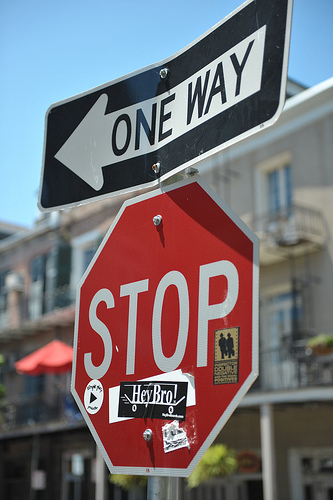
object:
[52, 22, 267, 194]
arrow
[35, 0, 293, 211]
sign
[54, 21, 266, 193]
words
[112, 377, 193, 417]
sticker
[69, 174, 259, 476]
sign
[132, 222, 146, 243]
light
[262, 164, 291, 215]
window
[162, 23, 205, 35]
sky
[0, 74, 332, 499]
building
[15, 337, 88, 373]
red umbrella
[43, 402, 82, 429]
balcony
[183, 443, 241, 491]
hanging flowers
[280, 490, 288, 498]
street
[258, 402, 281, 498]
white pole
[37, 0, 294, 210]
one way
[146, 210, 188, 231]
bolt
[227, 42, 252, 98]
black letters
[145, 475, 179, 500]
pole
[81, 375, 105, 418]
sticker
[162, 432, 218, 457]
decal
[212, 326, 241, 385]
sticker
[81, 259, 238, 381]
stop